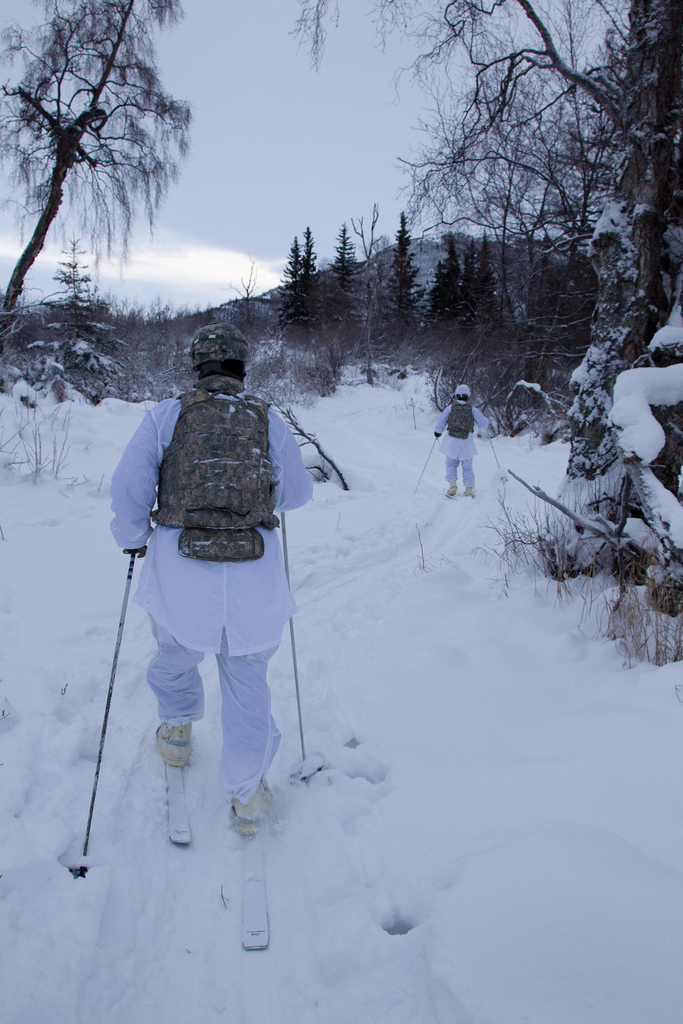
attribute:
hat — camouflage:
[163, 314, 269, 387]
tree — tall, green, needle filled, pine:
[258, 214, 326, 335]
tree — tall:
[17, 81, 128, 272]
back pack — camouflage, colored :
[125, 381, 302, 549]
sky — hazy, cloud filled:
[177, 155, 365, 256]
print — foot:
[344, 877, 494, 947]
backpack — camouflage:
[141, 388, 333, 590]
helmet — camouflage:
[167, 305, 277, 380]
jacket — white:
[107, 391, 314, 655]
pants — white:
[146, 616, 281, 804]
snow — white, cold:
[1, 342, 682, 1022]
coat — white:
[107, 393, 314, 658]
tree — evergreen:
[285, 234, 304, 312]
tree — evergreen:
[286, 224, 328, 343]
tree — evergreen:
[327, 221, 358, 315]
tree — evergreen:
[377, 210, 425, 335]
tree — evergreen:
[429, 233, 462, 319]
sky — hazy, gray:
[2, 0, 627, 317]